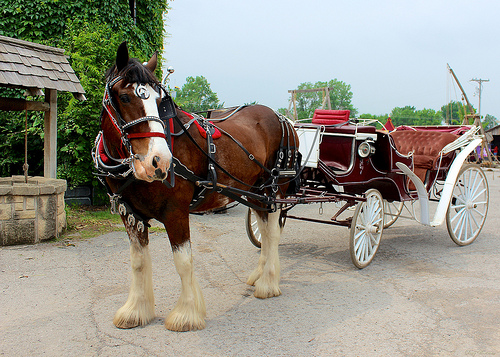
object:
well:
[0, 36, 88, 249]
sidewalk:
[0, 168, 500, 356]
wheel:
[348, 187, 385, 271]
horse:
[90, 38, 302, 332]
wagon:
[245, 109, 489, 270]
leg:
[163, 218, 207, 332]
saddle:
[181, 110, 221, 139]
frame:
[285, 87, 334, 123]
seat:
[388, 124, 478, 191]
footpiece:
[395, 138, 484, 227]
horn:
[357, 141, 376, 158]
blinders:
[158, 96, 177, 121]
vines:
[0, 0, 173, 190]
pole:
[469, 78, 490, 114]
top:
[173, 75, 359, 118]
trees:
[172, 75, 499, 134]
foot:
[164, 290, 210, 333]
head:
[101, 41, 173, 183]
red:
[389, 130, 456, 190]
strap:
[127, 132, 166, 139]